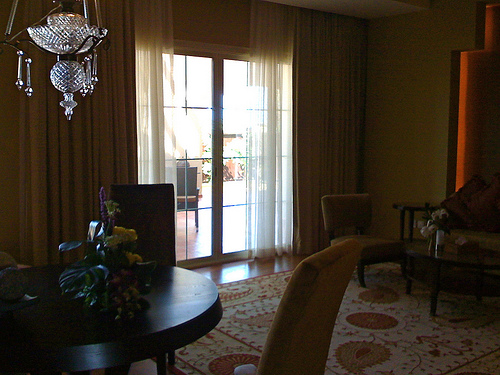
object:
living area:
[8, 7, 497, 374]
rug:
[426, 312, 494, 375]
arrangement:
[54, 182, 159, 321]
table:
[2, 257, 224, 375]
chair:
[254, 237, 361, 375]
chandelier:
[8, 7, 112, 127]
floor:
[145, 253, 499, 363]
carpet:
[231, 278, 272, 352]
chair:
[318, 184, 416, 293]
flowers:
[118, 244, 146, 269]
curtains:
[124, 14, 302, 279]